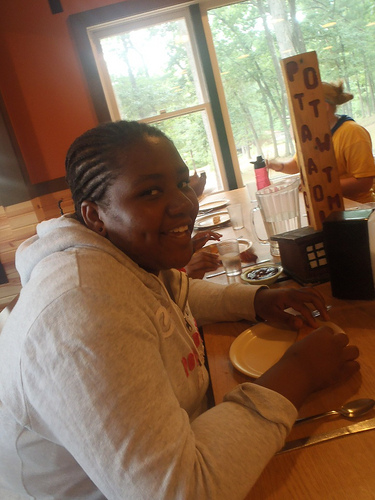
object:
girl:
[0, 120, 299, 498]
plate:
[229, 320, 346, 379]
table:
[291, 449, 373, 499]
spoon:
[295, 396, 367, 426]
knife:
[275, 416, 375, 454]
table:
[352, 302, 370, 337]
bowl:
[240, 264, 284, 286]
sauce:
[247, 266, 277, 280]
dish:
[229, 317, 348, 378]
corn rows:
[64, 134, 108, 195]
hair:
[57, 120, 170, 226]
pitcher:
[255, 173, 309, 258]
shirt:
[0, 212, 299, 500]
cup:
[216, 237, 243, 276]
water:
[220, 252, 241, 277]